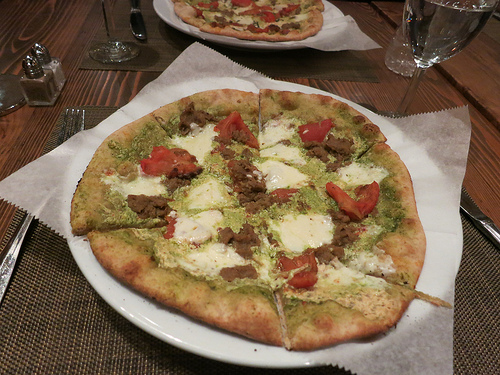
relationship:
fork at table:
[4, 86, 105, 293] [18, 15, 499, 364]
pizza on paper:
[104, 104, 407, 299] [18, 15, 499, 364]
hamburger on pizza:
[203, 134, 304, 222] [104, 104, 407, 299]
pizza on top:
[104, 104, 407, 299] [18, 15, 499, 364]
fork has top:
[4, 86, 105, 293] [48, 99, 101, 153]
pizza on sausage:
[104, 104, 407, 299] [91, 173, 206, 242]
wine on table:
[388, 8, 485, 118] [18, 15, 499, 364]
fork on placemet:
[4, 86, 105, 293] [18, 15, 499, 364]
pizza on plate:
[104, 104, 407, 299] [71, 107, 460, 363]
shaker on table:
[12, 33, 99, 102] [18, 15, 499, 364]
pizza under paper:
[104, 104, 407, 299] [138, 62, 202, 106]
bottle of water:
[363, 17, 466, 87] [388, 8, 485, 118]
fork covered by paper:
[4, 86, 105, 293] [5, 152, 71, 244]